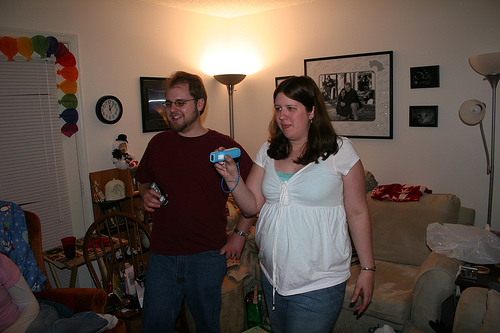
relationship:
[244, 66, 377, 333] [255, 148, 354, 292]
woman wearing shirt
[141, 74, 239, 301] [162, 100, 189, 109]
man wearing glasses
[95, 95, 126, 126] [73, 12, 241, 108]
clock on wall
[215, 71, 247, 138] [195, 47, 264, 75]
lamp shining light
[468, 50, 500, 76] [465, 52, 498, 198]
lamp shade on a lamp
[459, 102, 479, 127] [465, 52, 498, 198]
lamp shade on lamp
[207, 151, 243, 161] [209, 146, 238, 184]
remote in hand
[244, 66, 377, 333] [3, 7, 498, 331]
woman standing in a living room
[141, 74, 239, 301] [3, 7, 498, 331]
man standing in a living room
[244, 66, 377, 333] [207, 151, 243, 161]
woman holding remote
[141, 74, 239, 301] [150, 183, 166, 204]
man holding remote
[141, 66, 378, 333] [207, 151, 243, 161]
man and woman holding remote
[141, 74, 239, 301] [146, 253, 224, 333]
man wearing jeans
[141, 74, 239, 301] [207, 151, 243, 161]
man holding remote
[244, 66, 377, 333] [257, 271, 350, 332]
woman wearing jeans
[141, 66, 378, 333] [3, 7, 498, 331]
man and woman are standing in a living room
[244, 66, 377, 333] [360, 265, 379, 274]
woman wearing a wrist watch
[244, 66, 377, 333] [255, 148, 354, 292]
woman wearing a shirt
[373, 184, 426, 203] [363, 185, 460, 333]
blanket on couch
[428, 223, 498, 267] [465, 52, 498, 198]
plastic bag near lamp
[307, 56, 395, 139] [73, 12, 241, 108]
picture hanging on wall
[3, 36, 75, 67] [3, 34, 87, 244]
decorative cut out around window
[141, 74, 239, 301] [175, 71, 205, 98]
man has hair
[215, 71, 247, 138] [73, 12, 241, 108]
lamp near wall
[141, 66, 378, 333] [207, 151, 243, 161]
man and woman are playing with remote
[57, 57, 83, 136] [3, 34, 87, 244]
balloons around window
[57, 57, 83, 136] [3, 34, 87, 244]
balloons are around window